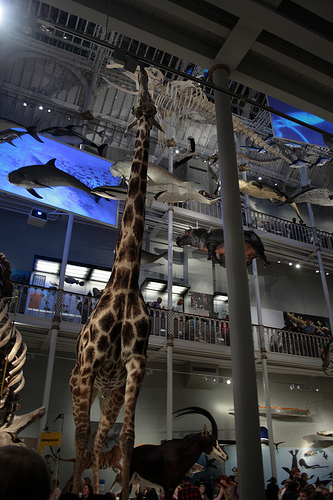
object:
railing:
[8, 280, 330, 359]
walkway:
[8, 312, 333, 377]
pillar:
[212, 68, 265, 499]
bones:
[102, 58, 292, 164]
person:
[303, 320, 315, 343]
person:
[44, 301, 51, 311]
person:
[289, 217, 299, 241]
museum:
[0, 0, 333, 500]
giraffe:
[68, 69, 166, 500]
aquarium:
[0, 118, 120, 229]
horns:
[171, 406, 218, 438]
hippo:
[176, 226, 271, 269]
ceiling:
[0, 0, 333, 164]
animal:
[7, 158, 111, 203]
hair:
[219, 475, 231, 490]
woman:
[213, 474, 238, 499]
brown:
[113, 267, 130, 292]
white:
[125, 357, 142, 404]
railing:
[177, 197, 333, 251]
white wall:
[19, 357, 333, 494]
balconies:
[0, 42, 333, 377]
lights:
[34, 258, 228, 312]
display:
[0, 0, 333, 500]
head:
[125, 69, 166, 133]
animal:
[128, 406, 229, 499]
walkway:
[115, 197, 333, 275]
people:
[77, 292, 230, 345]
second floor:
[0, 201, 331, 366]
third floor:
[144, 135, 333, 272]